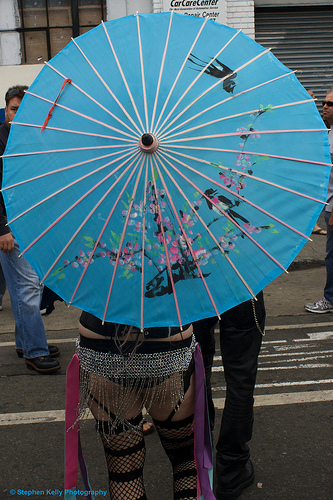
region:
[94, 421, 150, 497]
a fish net stockings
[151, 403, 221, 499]
a fish net stockings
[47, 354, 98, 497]
the ribbons are colorful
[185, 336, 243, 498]
the ribbons are colorful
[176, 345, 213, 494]
the ribbons are colorful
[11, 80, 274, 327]
the umbrella is blue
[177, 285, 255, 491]
the pants is black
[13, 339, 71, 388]
the shoes are black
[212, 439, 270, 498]
the shoes are black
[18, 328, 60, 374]
the shoes are black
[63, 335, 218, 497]
womn wearing fish net stockings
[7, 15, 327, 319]
The umbrella is blue.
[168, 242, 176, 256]
The flower is pink.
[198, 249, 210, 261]
The flower is white.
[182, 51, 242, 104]
a black bird.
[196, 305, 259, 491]
The pants are black.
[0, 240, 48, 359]
The pants are jeans.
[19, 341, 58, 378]
the shoes are black.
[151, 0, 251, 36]
The building is brick and white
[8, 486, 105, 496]
The lettering is blue.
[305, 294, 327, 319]
The shoes are white.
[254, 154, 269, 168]
part of an umbrellla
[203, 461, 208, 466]
part of a curtain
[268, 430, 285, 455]
side of a road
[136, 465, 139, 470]
back of a leg